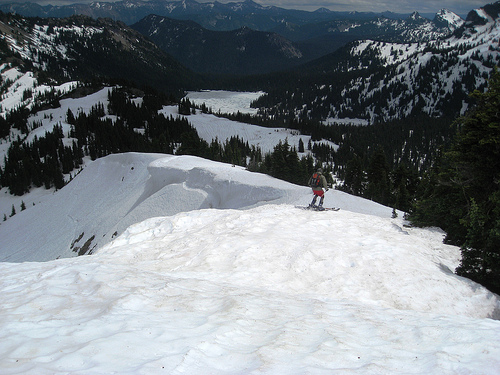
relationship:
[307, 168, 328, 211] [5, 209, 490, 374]
person on hill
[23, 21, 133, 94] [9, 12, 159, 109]
snow on mountainside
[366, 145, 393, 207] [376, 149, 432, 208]
tree has thick foliage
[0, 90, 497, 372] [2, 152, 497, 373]
snow covering ground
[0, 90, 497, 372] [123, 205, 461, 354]
snow covering ground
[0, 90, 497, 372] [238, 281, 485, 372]
snow covering ground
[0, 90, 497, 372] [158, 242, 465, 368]
snow covering ground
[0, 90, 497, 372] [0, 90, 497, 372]
snow covering snow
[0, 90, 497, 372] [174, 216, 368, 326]
snow covering ground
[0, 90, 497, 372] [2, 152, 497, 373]
snow on ground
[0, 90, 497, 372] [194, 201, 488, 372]
snow on ground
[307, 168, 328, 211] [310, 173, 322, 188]
person wearing backpack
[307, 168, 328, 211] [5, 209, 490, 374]
person looking at hill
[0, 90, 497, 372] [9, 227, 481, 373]
snow on ground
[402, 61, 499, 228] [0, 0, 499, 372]
trees not covered by snow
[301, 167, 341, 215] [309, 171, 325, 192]
person wearing jacket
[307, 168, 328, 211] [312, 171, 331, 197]
person wearing jacket